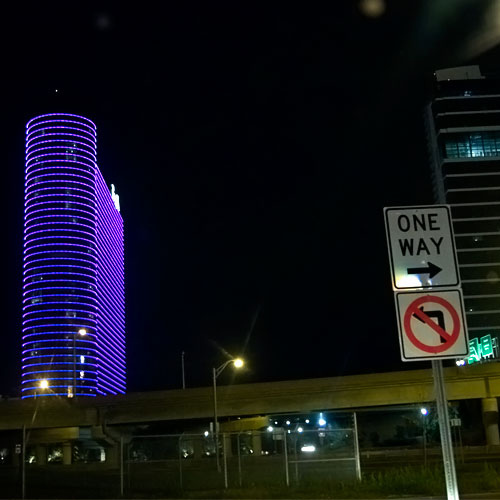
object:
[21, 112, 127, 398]
skyscrapers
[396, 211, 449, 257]
one-way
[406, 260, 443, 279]
arrow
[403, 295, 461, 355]
red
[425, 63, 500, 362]
building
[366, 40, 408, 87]
black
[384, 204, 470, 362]
white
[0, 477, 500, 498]
street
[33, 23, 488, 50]
sky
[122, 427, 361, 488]
fence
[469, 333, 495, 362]
green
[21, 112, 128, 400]
neon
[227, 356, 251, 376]
lamp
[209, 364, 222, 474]
pole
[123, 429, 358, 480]
chain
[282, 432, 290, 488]
aluminum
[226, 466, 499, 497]
weeds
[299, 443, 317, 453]
headlights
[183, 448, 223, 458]
cars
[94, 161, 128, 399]
side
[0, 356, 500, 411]
roadway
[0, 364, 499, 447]
bridge